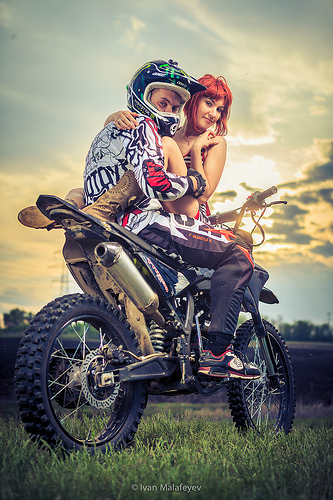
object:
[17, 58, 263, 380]
couple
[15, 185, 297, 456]
motorcycle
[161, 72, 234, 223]
woman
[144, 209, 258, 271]
lap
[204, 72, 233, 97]
red hair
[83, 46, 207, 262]
man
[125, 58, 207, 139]
helmet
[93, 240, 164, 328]
exhaust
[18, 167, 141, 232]
boots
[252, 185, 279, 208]
handle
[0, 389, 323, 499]
grass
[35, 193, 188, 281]
sit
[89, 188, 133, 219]
straps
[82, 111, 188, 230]
shirt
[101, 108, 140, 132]
hand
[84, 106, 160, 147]
shoulder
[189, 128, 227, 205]
arm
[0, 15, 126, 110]
sky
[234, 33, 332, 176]
sky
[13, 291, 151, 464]
tire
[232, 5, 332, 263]
clouds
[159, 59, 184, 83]
green writing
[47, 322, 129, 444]
spokes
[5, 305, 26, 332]
tree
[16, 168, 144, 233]
shoes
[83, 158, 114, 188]
black writing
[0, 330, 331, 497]
ground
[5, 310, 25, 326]
leaves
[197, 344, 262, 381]
shoe